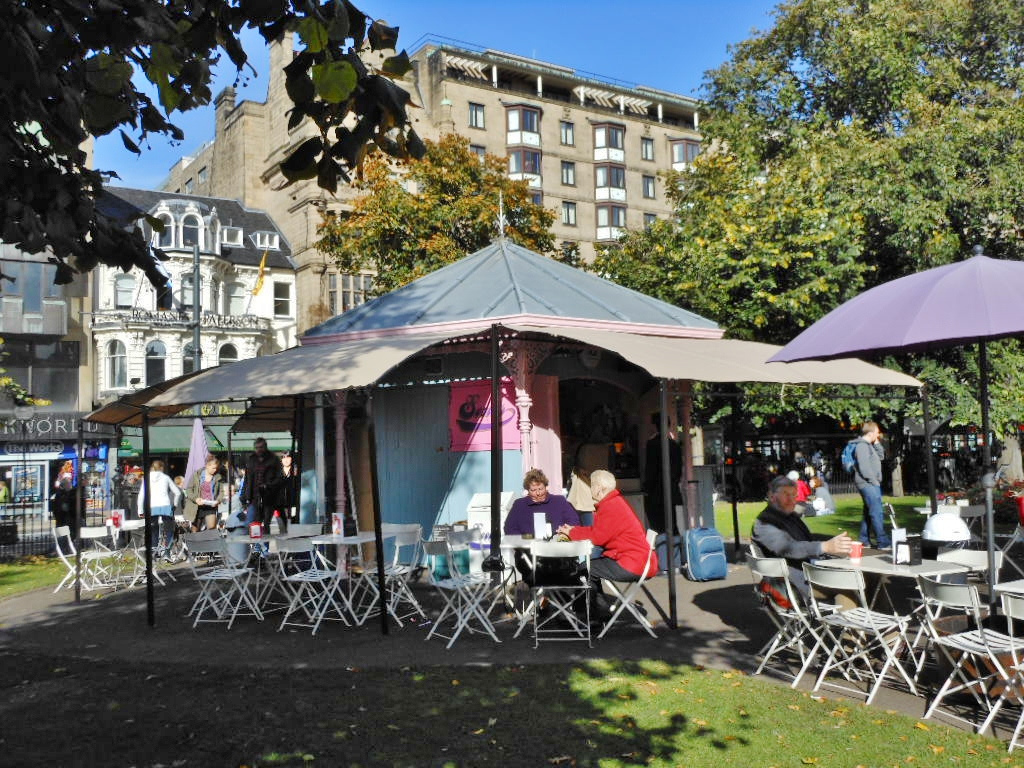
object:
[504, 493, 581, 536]
jacket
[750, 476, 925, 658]
man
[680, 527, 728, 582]
backpack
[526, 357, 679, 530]
wall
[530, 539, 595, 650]
chair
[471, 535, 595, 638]
table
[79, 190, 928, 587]
building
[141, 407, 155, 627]
pole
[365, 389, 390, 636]
pole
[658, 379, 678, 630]
pole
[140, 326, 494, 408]
awning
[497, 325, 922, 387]
awning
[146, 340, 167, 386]
window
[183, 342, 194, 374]
window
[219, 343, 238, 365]
window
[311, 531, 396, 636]
table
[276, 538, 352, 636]
chairs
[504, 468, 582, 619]
person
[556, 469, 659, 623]
person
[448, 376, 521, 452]
sign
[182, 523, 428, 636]
tent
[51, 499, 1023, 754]
chairs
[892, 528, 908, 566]
napkins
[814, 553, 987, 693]
table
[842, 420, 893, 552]
man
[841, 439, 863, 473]
backpack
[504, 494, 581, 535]
shirt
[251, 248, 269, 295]
flag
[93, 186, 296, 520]
building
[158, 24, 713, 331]
building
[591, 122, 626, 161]
window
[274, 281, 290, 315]
window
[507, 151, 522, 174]
window